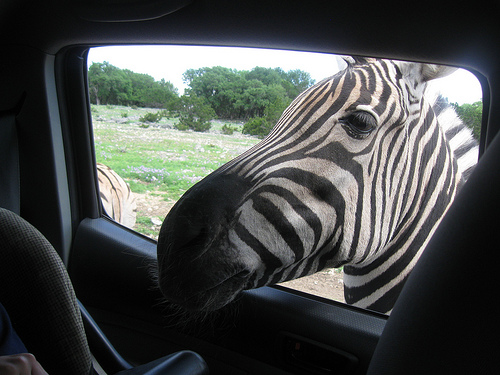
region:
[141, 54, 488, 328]
head of zebra in window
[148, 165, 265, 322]
muzzle of zebra is black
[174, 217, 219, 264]
nostril of zebra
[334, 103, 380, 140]
eye of zebra is black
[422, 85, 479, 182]
mane of zebra is white and dark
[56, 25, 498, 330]
the window of a car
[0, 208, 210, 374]
a car sit of baby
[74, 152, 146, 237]
a zebra behind a car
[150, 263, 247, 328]
mouth of zebra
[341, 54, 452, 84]
ears of zebra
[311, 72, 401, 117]
brown staining in zebra's fur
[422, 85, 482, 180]
black and white striped mane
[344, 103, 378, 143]
black rimmed eye of zebra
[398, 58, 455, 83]
lower half of ear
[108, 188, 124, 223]
a portion of a zebra tail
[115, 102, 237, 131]
short bushes in the distance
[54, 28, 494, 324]
an open car window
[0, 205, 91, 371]
the side of a car seat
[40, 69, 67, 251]
a hanging seat belt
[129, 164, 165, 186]
a small gray patch on the ground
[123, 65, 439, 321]
the zebra is black and white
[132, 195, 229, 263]
the nose is black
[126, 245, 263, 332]
the mouth is closed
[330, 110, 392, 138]
the eye is black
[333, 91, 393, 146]
the eye is open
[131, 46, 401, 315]
the zebra is in the car window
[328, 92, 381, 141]
the eyelashes are long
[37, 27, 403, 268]
the window is open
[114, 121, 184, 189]
the grass is short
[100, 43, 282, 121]
the sky is overcast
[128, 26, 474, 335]
The zebra is poking his head in the window.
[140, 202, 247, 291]
His nose is black.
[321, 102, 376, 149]
His eye is black.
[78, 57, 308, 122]
The trees are green.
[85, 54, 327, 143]
The trees are leafy.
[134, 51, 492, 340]
The zebra is black and white.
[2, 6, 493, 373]
The window is open.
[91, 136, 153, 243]
The zebra is walking away.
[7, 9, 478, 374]
The zebra is looking through.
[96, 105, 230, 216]
The grass is sparse.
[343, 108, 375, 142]
the left eye of a zebra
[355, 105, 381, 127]
the eyelashes on a zebra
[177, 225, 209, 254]
the left nostril of a zebra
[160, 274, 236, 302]
the zebra's closed mouth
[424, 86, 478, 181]
the zebra's mane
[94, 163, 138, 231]
the back end of a zebra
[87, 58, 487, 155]
green trees in the distance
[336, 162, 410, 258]
the flat cheek of a zebra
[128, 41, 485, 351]
a zebra head in window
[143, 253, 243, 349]
the mouth is hairy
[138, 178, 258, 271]
the nose is black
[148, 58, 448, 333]
a zebra has head in a car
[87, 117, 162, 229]
the butt of a zebra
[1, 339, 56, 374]
a person's hand in car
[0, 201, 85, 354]
a cloth back of carseat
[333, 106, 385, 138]
the eye of zebra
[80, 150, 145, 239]
Hilarious zebra's rear end.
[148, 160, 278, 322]
Zebra's nose in a car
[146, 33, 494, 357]
Zebra head in a car window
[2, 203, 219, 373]
Partially visible car seat